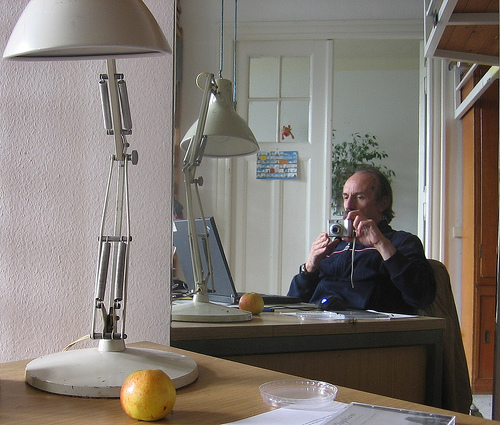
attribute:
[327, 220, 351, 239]
camera — small, silver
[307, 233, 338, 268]
hand — large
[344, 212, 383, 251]
hand — large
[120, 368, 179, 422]
grapefruit — bruised, red, yellow, large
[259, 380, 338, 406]
bowl — glass, clear, plastic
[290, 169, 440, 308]
man — balding, photographing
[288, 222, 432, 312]
pull over — dark blue, blue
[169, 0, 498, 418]
mirror — large, square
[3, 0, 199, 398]
lamp — pixar style, white, adjustable, silver, steel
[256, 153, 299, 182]
sign — blue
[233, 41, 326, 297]
door — closed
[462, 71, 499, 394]
cabinet — tall, wood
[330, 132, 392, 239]
houseplant — large, green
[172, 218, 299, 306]
lap top — black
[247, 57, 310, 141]
panes — glass